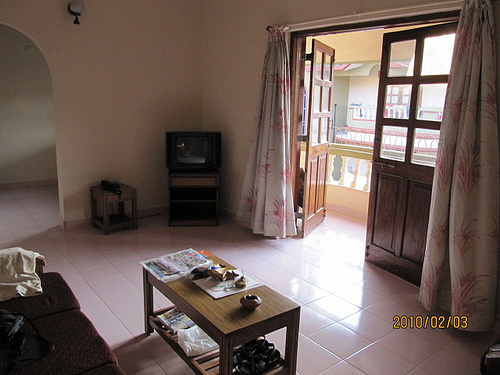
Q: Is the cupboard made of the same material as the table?
A: Yes, both the cupboard and the table are made of wood.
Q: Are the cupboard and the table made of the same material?
A: Yes, both the cupboard and the table are made of wood.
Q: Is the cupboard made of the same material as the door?
A: Yes, both the cupboard and the door are made of wood.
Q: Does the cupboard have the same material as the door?
A: Yes, both the cupboard and the door are made of wood.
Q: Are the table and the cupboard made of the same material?
A: Yes, both the table and the cupboard are made of wood.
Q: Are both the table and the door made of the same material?
A: Yes, both the table and the door are made of wood.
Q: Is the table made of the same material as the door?
A: Yes, both the table and the door are made of wood.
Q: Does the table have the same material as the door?
A: Yes, both the table and the door are made of wood.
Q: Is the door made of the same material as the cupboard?
A: Yes, both the door and the cupboard are made of wood.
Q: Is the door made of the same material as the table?
A: Yes, both the door and the table are made of wood.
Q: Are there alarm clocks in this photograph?
A: No, there are no alarm clocks.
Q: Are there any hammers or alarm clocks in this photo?
A: No, there are no alarm clocks or hammers.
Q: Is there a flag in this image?
A: No, there are no flags.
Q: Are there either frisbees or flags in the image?
A: No, there are no flags or frisbees.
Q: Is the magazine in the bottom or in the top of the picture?
A: The magazine is in the bottom of the image.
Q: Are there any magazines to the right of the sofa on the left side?
A: Yes, there is a magazine to the right of the sofa.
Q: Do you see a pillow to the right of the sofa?
A: No, there is a magazine to the right of the sofa.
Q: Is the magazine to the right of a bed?
A: No, the magazine is to the right of the sofa.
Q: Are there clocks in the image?
A: No, there are no clocks.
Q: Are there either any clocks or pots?
A: No, there are no clocks or pots.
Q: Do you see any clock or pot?
A: No, there are no clocks or pots.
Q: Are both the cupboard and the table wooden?
A: Yes, both the cupboard and the table are wooden.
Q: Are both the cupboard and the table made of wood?
A: Yes, both the cupboard and the table are made of wood.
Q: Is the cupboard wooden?
A: Yes, the cupboard is wooden.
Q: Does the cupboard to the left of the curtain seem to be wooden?
A: Yes, the cupboard is wooden.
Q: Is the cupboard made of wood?
A: Yes, the cupboard is made of wood.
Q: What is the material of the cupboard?
A: The cupboard is made of wood.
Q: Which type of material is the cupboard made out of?
A: The cupboard is made of wood.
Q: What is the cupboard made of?
A: The cupboard is made of wood.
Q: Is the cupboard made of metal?
A: No, the cupboard is made of wood.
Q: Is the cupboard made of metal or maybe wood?
A: The cupboard is made of wood.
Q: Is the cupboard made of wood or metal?
A: The cupboard is made of wood.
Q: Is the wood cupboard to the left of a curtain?
A: Yes, the cupboard is to the left of a curtain.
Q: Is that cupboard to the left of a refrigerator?
A: No, the cupboard is to the left of a curtain.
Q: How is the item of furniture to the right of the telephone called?
A: The piece of furniture is a cupboard.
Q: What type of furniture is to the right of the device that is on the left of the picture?
A: The piece of furniture is a cupboard.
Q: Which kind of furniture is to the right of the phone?
A: The piece of furniture is a cupboard.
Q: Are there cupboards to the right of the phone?
A: Yes, there is a cupboard to the right of the phone.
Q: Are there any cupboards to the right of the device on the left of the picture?
A: Yes, there is a cupboard to the right of the phone.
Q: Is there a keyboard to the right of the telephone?
A: No, there is a cupboard to the right of the telephone.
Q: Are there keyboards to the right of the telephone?
A: No, there is a cupboard to the right of the telephone.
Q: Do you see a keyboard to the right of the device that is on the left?
A: No, there is a cupboard to the right of the telephone.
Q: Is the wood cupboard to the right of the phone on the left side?
A: Yes, the cupboard is to the right of the telephone.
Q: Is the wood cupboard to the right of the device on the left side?
A: Yes, the cupboard is to the right of the telephone.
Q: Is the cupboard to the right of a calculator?
A: No, the cupboard is to the right of the telephone.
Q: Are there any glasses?
A: No, there are no glasses.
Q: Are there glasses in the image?
A: No, there are no glasses.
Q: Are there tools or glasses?
A: No, there are no glasses or tools.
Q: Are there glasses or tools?
A: No, there are no glasses or tools.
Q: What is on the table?
A: The paper is on the table.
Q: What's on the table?
A: The paper is on the table.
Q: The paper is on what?
A: The paper is on the table.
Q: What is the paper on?
A: The paper is on the table.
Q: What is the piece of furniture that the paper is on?
A: The piece of furniture is a table.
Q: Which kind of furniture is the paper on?
A: The paper is on the table.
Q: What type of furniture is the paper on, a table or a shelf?
A: The paper is on a table.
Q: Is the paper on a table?
A: Yes, the paper is on a table.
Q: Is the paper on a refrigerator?
A: No, the paper is on a table.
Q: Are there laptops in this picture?
A: No, there are no laptops.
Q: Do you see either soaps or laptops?
A: No, there are no laptops or soaps.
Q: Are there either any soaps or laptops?
A: No, there are no laptops or soaps.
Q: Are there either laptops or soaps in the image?
A: No, there are no laptops or soaps.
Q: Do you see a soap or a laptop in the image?
A: No, there are no laptops or soaps.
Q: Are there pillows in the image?
A: No, there are no pillows.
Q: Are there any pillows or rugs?
A: No, there are no pillows or rugs.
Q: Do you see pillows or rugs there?
A: No, there are no pillows or rugs.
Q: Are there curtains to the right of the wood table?
A: Yes, there are curtains to the right of the table.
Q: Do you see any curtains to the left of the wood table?
A: No, the curtains are to the right of the table.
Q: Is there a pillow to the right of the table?
A: No, there are curtains to the right of the table.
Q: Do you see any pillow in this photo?
A: No, there are no pillows.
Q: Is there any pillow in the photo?
A: No, there are no pillows.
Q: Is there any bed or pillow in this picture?
A: No, there are no pillows or beds.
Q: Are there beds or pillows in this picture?
A: No, there are no pillows or beds.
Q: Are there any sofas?
A: Yes, there is a sofa.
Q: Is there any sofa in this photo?
A: Yes, there is a sofa.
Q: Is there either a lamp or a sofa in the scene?
A: Yes, there is a sofa.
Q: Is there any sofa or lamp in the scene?
A: Yes, there is a sofa.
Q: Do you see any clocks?
A: No, there are no clocks.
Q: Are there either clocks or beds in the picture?
A: No, there are no clocks or beds.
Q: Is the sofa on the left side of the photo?
A: Yes, the sofa is on the left of the image.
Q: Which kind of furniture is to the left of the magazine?
A: The piece of furniture is a sofa.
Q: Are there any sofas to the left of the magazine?
A: Yes, there is a sofa to the left of the magazine.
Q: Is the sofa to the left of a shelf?
A: No, the sofa is to the left of a magazine.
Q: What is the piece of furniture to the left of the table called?
A: The piece of furniture is a sofa.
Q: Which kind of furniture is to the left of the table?
A: The piece of furniture is a sofa.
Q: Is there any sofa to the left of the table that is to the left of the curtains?
A: Yes, there is a sofa to the left of the table.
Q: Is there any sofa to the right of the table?
A: No, the sofa is to the left of the table.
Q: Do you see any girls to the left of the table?
A: No, there is a sofa to the left of the table.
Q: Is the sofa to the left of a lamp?
A: No, the sofa is to the left of a table.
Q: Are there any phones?
A: Yes, there is a phone.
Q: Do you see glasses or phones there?
A: Yes, there is a phone.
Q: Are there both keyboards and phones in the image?
A: No, there is a phone but no keyboards.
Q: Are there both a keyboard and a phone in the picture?
A: No, there is a phone but no keyboards.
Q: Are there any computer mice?
A: No, there are no computer mice.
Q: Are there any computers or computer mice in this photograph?
A: No, there are no computer mice or computers.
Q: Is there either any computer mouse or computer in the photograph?
A: No, there are no computer mice or computers.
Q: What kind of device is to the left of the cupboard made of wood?
A: The device is a phone.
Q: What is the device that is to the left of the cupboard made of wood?
A: The device is a phone.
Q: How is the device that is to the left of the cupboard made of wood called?
A: The device is a phone.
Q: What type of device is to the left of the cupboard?
A: The device is a phone.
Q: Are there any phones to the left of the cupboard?
A: Yes, there is a phone to the left of the cupboard.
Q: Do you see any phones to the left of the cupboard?
A: Yes, there is a phone to the left of the cupboard.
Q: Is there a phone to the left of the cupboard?
A: Yes, there is a phone to the left of the cupboard.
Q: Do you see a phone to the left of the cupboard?
A: Yes, there is a phone to the left of the cupboard.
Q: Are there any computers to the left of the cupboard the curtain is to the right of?
A: No, there is a phone to the left of the cupboard.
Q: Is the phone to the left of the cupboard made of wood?
A: Yes, the phone is to the left of the cupboard.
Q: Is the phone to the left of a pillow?
A: No, the phone is to the left of the cupboard.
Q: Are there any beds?
A: No, there are no beds.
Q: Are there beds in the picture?
A: No, there are no beds.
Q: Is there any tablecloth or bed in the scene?
A: No, there are no beds or tablecloths.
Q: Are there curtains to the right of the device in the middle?
A: Yes, there is a curtain to the right of the television.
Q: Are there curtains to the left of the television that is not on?
A: No, the curtain is to the right of the TV.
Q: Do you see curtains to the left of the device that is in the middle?
A: No, the curtain is to the right of the TV.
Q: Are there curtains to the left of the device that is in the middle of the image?
A: No, the curtain is to the right of the TV.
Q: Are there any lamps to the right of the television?
A: No, there is a curtain to the right of the television.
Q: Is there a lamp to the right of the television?
A: No, there is a curtain to the right of the television.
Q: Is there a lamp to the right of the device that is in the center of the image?
A: No, there is a curtain to the right of the television.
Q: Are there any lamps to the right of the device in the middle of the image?
A: No, there is a curtain to the right of the television.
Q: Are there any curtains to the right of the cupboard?
A: Yes, there is a curtain to the right of the cupboard.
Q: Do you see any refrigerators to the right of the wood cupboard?
A: No, there is a curtain to the right of the cupboard.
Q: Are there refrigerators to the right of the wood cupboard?
A: No, there is a curtain to the right of the cupboard.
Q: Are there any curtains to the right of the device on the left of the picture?
A: Yes, there is a curtain to the right of the telephone.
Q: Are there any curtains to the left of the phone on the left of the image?
A: No, the curtain is to the right of the phone.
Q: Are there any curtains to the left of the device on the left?
A: No, the curtain is to the right of the phone.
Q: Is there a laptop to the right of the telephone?
A: No, there is a curtain to the right of the telephone.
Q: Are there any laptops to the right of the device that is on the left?
A: No, there is a curtain to the right of the telephone.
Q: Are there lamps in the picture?
A: No, there are no lamps.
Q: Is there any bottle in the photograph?
A: No, there are no bottles.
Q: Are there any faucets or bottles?
A: No, there are no bottles or faucets.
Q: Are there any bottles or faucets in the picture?
A: No, there are no bottles or faucets.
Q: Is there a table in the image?
A: Yes, there is a table.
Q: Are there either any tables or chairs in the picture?
A: Yes, there is a table.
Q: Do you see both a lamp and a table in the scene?
A: No, there is a table but no lamps.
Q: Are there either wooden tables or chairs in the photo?
A: Yes, there is a wood table.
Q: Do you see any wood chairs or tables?
A: Yes, there is a wood table.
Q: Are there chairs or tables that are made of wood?
A: Yes, the table is made of wood.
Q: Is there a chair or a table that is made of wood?
A: Yes, the table is made of wood.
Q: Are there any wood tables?
A: Yes, there is a wood table.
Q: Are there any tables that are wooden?
A: Yes, there is a table that is wooden.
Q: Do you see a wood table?
A: Yes, there is a table that is made of wood.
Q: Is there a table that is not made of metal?
A: Yes, there is a table that is made of wood.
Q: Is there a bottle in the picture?
A: No, there are no bottles.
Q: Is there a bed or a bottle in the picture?
A: No, there are no bottles or beds.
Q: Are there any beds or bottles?
A: No, there are no bottles or beds.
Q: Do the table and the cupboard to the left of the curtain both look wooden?
A: Yes, both the table and the cupboard are wooden.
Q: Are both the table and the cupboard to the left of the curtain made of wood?
A: Yes, both the table and the cupboard are made of wood.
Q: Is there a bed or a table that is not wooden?
A: No, there is a table but it is wooden.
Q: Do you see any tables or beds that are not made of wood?
A: No, there is a table but it is made of wood.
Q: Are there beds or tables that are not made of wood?
A: No, there is a table but it is made of wood.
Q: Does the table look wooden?
A: Yes, the table is wooden.